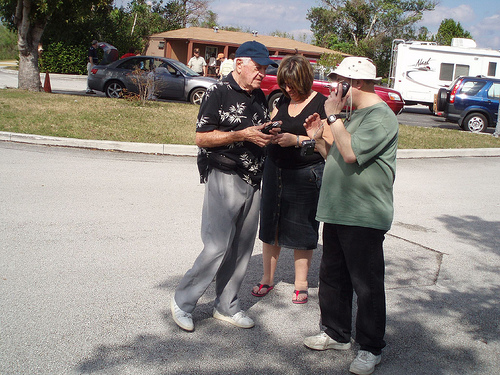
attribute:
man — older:
[170, 39, 283, 329]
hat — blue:
[234, 38, 279, 70]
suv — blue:
[437, 72, 499, 135]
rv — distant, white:
[386, 35, 498, 111]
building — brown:
[140, 25, 356, 82]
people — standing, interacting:
[188, 45, 235, 81]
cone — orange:
[42, 67, 53, 94]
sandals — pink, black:
[250, 280, 309, 306]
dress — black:
[256, 88, 326, 248]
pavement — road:
[1, 139, 499, 374]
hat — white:
[326, 54, 381, 83]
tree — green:
[321, 38, 366, 73]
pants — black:
[318, 223, 387, 356]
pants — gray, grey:
[173, 167, 261, 317]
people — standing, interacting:
[168, 39, 398, 374]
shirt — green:
[314, 100, 399, 232]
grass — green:
[0, 85, 499, 148]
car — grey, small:
[86, 54, 220, 104]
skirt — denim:
[257, 155, 323, 250]